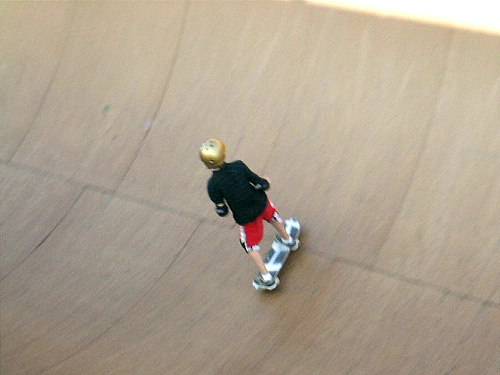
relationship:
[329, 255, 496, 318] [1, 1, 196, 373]
line on ramp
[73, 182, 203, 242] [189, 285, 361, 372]
line on ramp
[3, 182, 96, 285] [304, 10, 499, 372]
line on ramp